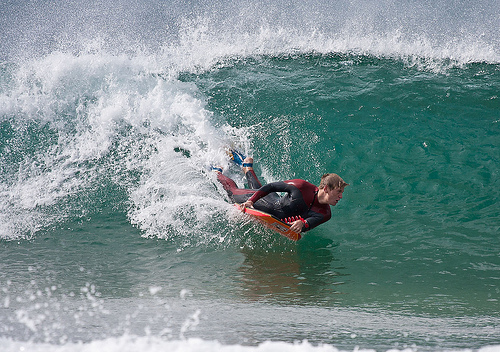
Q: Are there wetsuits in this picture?
A: Yes, there is a wetsuit.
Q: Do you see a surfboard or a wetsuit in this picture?
A: Yes, there is a wetsuit.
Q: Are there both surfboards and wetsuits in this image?
A: Yes, there are both a wetsuit and a surfboard.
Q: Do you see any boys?
A: No, there are no boys.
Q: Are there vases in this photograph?
A: No, there are no vases.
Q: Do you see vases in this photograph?
A: No, there are no vases.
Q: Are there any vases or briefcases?
A: No, there are no vases or briefcases.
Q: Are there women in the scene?
A: No, there are no women.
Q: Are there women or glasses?
A: No, there are no women or glasses.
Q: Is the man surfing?
A: Yes, the man is surfing.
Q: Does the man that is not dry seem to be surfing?
A: Yes, the man is surfing.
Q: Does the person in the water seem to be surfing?
A: Yes, the man is surfing.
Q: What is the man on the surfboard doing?
A: The man is surfing.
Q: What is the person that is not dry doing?
A: The man is surfing.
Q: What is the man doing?
A: The man is surfing.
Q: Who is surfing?
A: The man is surfing.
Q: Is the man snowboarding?
A: No, the man is surfing.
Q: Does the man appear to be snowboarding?
A: No, the man is surfing.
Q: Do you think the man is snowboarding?
A: No, the man is surfing.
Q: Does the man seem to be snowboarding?
A: No, the man is surfing.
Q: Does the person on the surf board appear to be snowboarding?
A: No, the man is surfing.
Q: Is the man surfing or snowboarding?
A: The man is surfing.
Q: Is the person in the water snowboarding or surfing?
A: The man is surfing.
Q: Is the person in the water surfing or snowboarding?
A: The man is surfing.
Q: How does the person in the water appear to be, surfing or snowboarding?
A: The man is surfing.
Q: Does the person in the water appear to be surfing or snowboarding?
A: The man is surfing.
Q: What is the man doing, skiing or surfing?
A: The man is surfing.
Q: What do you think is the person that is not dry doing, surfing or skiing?
A: The man is surfing.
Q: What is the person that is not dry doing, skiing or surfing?
A: The man is surfing.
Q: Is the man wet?
A: Yes, the man is wet.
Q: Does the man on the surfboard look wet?
A: Yes, the man is wet.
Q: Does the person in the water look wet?
A: Yes, the man is wet.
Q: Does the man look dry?
A: No, the man is wet.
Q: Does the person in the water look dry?
A: No, the man is wet.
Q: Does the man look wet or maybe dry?
A: The man is wet.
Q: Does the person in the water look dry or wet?
A: The man is wet.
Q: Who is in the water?
A: The man is in the water.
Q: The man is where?
A: The man is in the water.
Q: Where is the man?
A: The man is in the water.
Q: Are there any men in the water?
A: Yes, there is a man in the water.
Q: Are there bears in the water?
A: No, there is a man in the water.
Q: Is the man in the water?
A: Yes, the man is in the water.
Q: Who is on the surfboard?
A: The man is on the surfboard.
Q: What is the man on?
A: The man is on the surfboard.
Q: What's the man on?
A: The man is on the surfboard.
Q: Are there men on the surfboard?
A: Yes, there is a man on the surfboard.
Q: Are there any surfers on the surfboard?
A: No, there is a man on the surfboard.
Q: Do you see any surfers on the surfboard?
A: No, there is a man on the surfboard.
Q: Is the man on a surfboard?
A: Yes, the man is on a surfboard.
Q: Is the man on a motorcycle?
A: No, the man is on a surfboard.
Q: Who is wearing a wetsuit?
A: The man is wearing a wetsuit.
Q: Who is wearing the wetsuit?
A: The man is wearing a wetsuit.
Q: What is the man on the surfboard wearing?
A: The man is wearing a wetsuit.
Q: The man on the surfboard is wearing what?
A: The man is wearing a wetsuit.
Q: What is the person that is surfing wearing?
A: The man is wearing a wetsuit.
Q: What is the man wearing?
A: The man is wearing a wetsuit.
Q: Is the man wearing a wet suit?
A: Yes, the man is wearing a wet suit.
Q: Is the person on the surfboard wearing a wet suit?
A: Yes, the man is wearing a wet suit.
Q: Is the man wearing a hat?
A: No, the man is wearing a wet suit.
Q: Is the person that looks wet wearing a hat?
A: No, the man is wearing a wet suit.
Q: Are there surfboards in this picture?
A: Yes, there is a surfboard.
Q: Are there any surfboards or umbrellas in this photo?
A: Yes, there is a surfboard.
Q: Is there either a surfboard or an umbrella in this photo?
A: Yes, there is a surfboard.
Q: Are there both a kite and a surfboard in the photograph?
A: No, there is a surfboard but no kites.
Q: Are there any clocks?
A: No, there are no clocks.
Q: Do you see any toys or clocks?
A: No, there are no clocks or toys.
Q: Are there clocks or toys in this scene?
A: No, there are no clocks or toys.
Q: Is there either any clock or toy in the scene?
A: No, there are no clocks or toys.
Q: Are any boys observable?
A: No, there are no boys.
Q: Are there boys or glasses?
A: No, there are no boys or glasses.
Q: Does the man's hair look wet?
A: Yes, the hair is wet.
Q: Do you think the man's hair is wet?
A: Yes, the hair is wet.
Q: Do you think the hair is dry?
A: No, the hair is wet.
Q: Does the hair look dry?
A: No, the hair is wet.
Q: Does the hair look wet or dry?
A: The hair is wet.